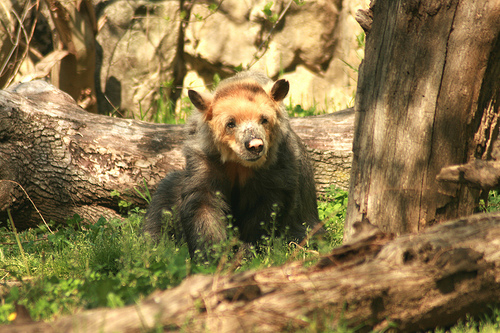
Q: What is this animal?
A: A bear.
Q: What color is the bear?
A: Brown.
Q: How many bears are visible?
A: One.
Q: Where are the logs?
A: In front and behind the bear.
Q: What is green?
A: The grass.